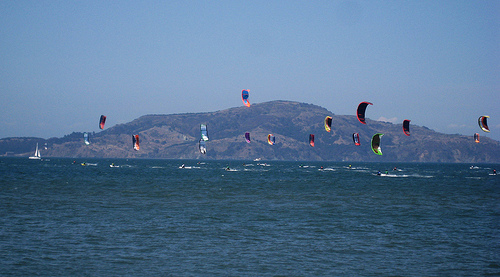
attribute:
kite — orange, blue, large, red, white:
[239, 87, 253, 114]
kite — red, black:
[357, 99, 374, 127]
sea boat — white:
[28, 139, 44, 160]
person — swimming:
[70, 159, 80, 168]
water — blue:
[4, 164, 497, 271]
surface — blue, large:
[2, 157, 498, 268]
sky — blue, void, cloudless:
[6, 10, 499, 143]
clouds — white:
[378, 110, 486, 136]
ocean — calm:
[4, 165, 500, 272]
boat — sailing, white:
[27, 144, 47, 166]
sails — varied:
[41, 88, 495, 168]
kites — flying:
[41, 81, 491, 161]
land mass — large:
[6, 100, 499, 163]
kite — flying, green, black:
[369, 129, 387, 158]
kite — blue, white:
[201, 123, 212, 146]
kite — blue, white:
[199, 139, 207, 157]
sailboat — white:
[28, 142, 44, 161]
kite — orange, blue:
[267, 126, 278, 149]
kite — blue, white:
[83, 130, 93, 149]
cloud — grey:
[367, 107, 454, 136]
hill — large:
[10, 101, 500, 160]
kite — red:
[307, 130, 322, 152]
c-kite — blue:
[198, 122, 208, 142]